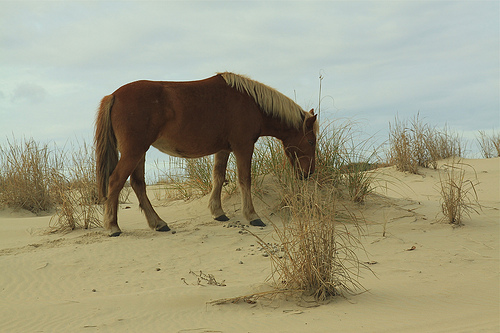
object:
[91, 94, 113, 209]
tail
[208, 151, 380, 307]
bunch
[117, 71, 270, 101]
back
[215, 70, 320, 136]
mane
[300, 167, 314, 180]
nose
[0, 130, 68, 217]
grass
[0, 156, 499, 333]
hill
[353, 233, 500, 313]
sand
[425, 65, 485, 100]
sky clouds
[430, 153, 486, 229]
bush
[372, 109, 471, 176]
bush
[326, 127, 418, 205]
bush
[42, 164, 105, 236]
bush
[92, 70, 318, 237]
horse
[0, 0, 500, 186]
sky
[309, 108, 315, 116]
ear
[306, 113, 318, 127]
ear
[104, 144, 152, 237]
leg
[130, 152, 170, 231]
leg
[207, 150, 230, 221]
leg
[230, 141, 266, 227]
leg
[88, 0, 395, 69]
clouds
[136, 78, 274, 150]
body